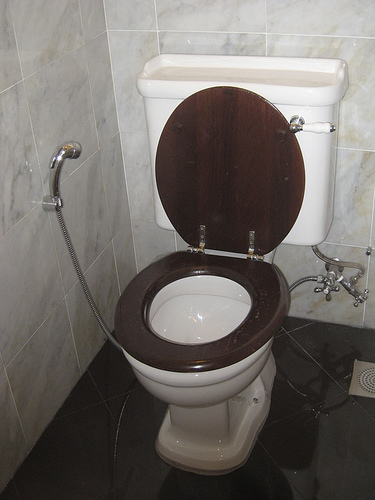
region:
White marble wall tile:
[3, 190, 53, 421]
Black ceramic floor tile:
[269, 403, 372, 498]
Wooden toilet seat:
[117, 236, 295, 382]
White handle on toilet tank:
[286, 110, 339, 143]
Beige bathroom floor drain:
[344, 350, 374, 404]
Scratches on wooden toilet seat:
[220, 288, 278, 369]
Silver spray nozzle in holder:
[31, 133, 104, 233]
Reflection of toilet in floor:
[261, 383, 352, 497]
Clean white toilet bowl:
[167, 300, 228, 345]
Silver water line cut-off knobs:
[300, 255, 370, 321]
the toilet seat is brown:
[143, 204, 261, 336]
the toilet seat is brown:
[87, 202, 364, 431]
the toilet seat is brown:
[124, 259, 253, 385]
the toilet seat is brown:
[54, 98, 320, 475]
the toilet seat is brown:
[116, 211, 252, 490]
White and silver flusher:
[286, 114, 335, 139]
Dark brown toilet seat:
[112, 238, 280, 377]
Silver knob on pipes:
[313, 269, 371, 308]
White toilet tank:
[123, 52, 348, 247]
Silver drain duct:
[353, 358, 373, 398]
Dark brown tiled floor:
[26, 298, 373, 499]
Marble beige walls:
[2, 0, 374, 488]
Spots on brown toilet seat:
[249, 284, 277, 350]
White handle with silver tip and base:
[288, 119, 339, 136]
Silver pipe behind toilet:
[46, 129, 373, 378]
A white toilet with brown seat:
[51, 42, 350, 469]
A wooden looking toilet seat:
[109, 92, 311, 380]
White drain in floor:
[346, 354, 373, 397]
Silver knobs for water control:
[299, 264, 369, 320]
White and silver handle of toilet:
[283, 117, 333, 142]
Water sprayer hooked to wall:
[49, 135, 95, 215]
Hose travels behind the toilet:
[51, 207, 339, 378]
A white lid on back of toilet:
[136, 42, 357, 110]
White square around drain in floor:
[342, 353, 374, 403]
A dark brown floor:
[0, 274, 371, 498]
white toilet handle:
[285, 110, 340, 137]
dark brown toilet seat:
[112, 246, 293, 376]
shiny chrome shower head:
[44, 135, 85, 226]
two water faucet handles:
[308, 274, 371, 310]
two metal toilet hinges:
[178, 222, 271, 262]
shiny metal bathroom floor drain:
[342, 351, 374, 404]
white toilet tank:
[141, 46, 339, 247]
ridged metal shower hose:
[49, 203, 113, 355]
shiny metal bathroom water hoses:
[290, 247, 370, 308]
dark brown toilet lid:
[150, 82, 308, 257]